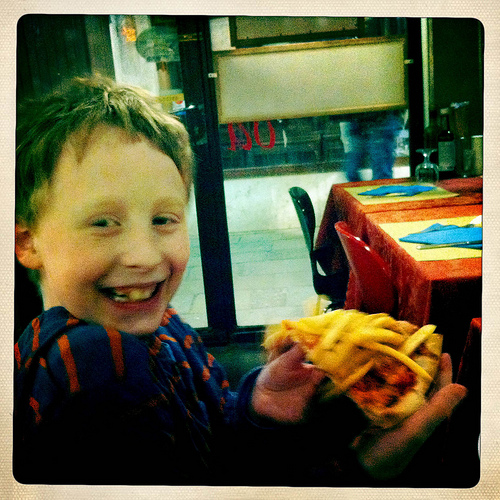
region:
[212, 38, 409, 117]
a sign hanging on the door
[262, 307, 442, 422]
a slice of pizza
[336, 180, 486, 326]
a table with a red table cloth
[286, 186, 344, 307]
a dark colored chair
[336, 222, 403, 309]
the back of a red chair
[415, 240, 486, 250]
a silver knife that is on the table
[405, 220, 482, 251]
a blue napkin on the table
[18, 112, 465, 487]
a young boy smiling holding a piece of pizza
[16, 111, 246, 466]
a boy wearing a striped shirt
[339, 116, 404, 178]
someone standing outside the window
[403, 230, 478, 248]
blue colored paper napkin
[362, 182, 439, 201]
blue colored paper napkin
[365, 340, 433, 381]
golden colored french fry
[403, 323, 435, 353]
golden colored french fry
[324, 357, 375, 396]
golden colored french fry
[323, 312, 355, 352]
golden colored french fry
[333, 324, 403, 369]
golden colored french fry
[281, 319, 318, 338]
golden colored french fry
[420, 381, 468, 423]
small white child's finger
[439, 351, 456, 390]
small white child's finger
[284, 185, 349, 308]
a green chair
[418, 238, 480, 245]
a silver knife on the plate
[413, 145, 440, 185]
a wine glass turned upside down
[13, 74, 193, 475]
a smiling boy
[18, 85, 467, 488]
a boy holding a slice of pizza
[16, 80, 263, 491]
a boy wearing a orange and black sweater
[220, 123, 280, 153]
writing on the glass window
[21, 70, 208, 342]
Little boy grinning as he faces the camera.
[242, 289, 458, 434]
A pizza with french fries on it.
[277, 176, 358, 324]
A green chair with backing.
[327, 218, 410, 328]
A red chair with backing.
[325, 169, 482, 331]
A pair of tables with orange tablecloth.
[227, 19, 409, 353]
A large window with a board on it.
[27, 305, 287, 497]
A blue shirt with orange stripes.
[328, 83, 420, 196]
A pair of people conversing outside.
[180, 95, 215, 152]
A metal door handle.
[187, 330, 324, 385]
A floor with green carpet.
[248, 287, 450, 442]
there are french fries on the pizza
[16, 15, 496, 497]
he is holding a slice of pizza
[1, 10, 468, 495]
his slice of pizza is topped with fries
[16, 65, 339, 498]
he is wearing a blue hoodie with red stripes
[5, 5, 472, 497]
he is smiling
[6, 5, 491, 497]
he is eating in a restaurant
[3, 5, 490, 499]
he is eating pizza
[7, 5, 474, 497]
he is having a slice of pizza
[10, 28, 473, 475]
he is holding his pizza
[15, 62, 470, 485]
he is holding his slice of pizza